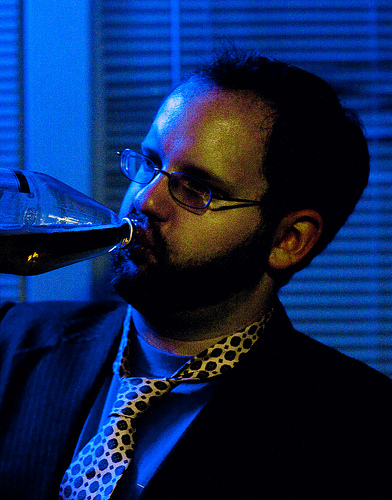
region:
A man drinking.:
[4, 44, 390, 499]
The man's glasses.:
[114, 147, 285, 214]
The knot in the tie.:
[108, 377, 167, 416]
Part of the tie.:
[80, 465, 105, 491]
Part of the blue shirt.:
[149, 431, 169, 451]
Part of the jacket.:
[277, 428, 320, 473]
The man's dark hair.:
[303, 145, 332, 180]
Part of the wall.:
[56, 89, 76, 138]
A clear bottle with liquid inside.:
[0, 167, 142, 277]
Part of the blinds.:
[333, 290, 383, 331]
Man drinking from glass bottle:
[5, 25, 380, 345]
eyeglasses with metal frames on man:
[111, 146, 215, 210]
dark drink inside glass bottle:
[5, 219, 124, 276]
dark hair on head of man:
[272, 65, 370, 184]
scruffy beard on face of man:
[132, 228, 275, 309]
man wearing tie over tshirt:
[52, 335, 260, 495]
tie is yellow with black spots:
[80, 370, 170, 496]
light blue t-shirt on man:
[140, 424, 165, 457]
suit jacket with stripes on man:
[2, 299, 72, 496]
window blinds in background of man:
[106, 0, 389, 43]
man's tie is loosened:
[43, 308, 249, 498]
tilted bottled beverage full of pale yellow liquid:
[4, 156, 141, 282]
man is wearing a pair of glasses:
[113, 140, 288, 222]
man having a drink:
[5, 17, 380, 347]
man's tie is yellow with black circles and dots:
[67, 299, 263, 498]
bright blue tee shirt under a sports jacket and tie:
[73, 309, 234, 498]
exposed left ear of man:
[264, 202, 324, 277]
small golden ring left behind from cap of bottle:
[122, 214, 132, 245]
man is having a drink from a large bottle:
[2, 27, 372, 337]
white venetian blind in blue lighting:
[103, 13, 160, 94]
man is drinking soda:
[0, 34, 386, 478]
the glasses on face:
[107, 135, 247, 224]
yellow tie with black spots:
[34, 311, 249, 490]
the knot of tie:
[99, 362, 174, 410]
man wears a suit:
[0, 31, 387, 487]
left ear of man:
[262, 202, 329, 277]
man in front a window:
[3, 3, 387, 499]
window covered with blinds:
[96, 0, 388, 98]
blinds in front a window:
[93, 4, 389, 75]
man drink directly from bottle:
[6, 32, 390, 397]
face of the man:
[52, 34, 344, 475]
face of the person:
[88, 25, 388, 339]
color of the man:
[75, 287, 303, 457]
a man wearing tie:
[70, 370, 198, 496]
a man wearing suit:
[179, 398, 354, 493]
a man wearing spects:
[118, 148, 269, 257]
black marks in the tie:
[95, 412, 140, 460]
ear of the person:
[263, 190, 326, 299]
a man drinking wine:
[6, 159, 227, 325]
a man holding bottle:
[19, 155, 221, 334]